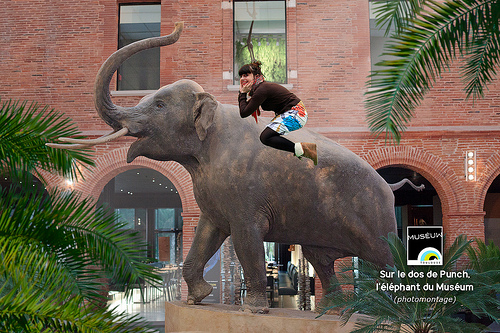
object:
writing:
[375, 268, 476, 280]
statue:
[43, 23, 428, 314]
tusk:
[59, 129, 128, 146]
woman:
[237, 60, 320, 163]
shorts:
[266, 100, 308, 136]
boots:
[296, 141, 320, 166]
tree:
[3, 99, 162, 332]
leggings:
[261, 127, 296, 153]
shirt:
[236, 80, 301, 119]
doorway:
[76, 162, 189, 303]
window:
[235, 2, 286, 85]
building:
[3, 0, 499, 319]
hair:
[235, 59, 264, 80]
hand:
[238, 83, 252, 93]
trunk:
[92, 22, 180, 123]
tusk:
[43, 140, 81, 151]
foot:
[186, 278, 217, 306]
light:
[467, 150, 476, 158]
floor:
[109, 284, 170, 319]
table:
[144, 262, 175, 293]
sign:
[406, 225, 444, 265]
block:
[166, 295, 422, 332]